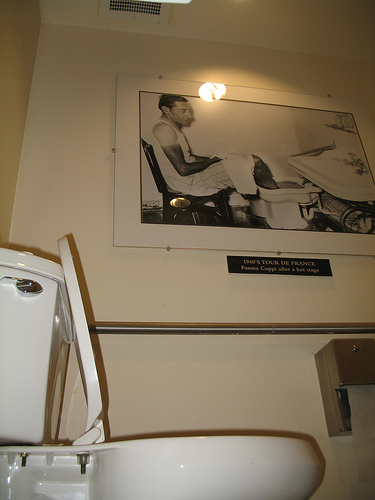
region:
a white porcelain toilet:
[0, 240, 332, 498]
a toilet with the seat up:
[44, 233, 337, 499]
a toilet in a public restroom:
[0, 197, 371, 495]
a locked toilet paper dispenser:
[310, 337, 373, 439]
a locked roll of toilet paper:
[310, 333, 373, 457]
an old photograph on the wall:
[88, 67, 373, 269]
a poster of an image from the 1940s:
[81, 63, 373, 285]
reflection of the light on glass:
[186, 72, 241, 127]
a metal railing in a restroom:
[88, 311, 373, 357]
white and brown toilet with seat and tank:
[1, 225, 329, 494]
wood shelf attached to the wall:
[312, 330, 370, 440]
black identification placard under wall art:
[208, 249, 336, 283]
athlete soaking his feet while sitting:
[110, 69, 374, 238]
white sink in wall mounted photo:
[274, 117, 369, 223]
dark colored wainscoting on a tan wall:
[88, 312, 370, 338]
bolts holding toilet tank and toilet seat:
[2, 438, 98, 476]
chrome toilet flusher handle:
[0, 269, 49, 302]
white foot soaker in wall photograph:
[236, 163, 321, 226]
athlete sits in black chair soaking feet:
[139, 94, 281, 222]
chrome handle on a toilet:
[0, 269, 48, 304]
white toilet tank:
[0, 240, 85, 452]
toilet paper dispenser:
[308, 323, 373, 444]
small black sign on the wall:
[223, 252, 336, 277]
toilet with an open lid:
[53, 227, 329, 499]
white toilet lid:
[52, 232, 112, 457]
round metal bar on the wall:
[75, 314, 374, 337]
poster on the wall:
[107, 78, 372, 255]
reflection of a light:
[193, 75, 230, 107]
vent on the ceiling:
[97, 2, 175, 31]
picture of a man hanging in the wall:
[110, 72, 374, 256]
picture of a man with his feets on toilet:
[116, 71, 374, 256]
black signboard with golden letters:
[228, 255, 332, 279]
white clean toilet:
[1, 232, 322, 498]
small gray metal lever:
[0, 273, 45, 294]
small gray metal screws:
[18, 450, 89, 473]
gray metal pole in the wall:
[76, 322, 373, 333]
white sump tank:
[0, 242, 76, 446]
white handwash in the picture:
[290, 142, 373, 205]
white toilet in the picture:
[247, 169, 330, 230]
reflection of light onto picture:
[194, 77, 230, 105]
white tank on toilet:
[3, 250, 57, 439]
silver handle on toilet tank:
[2, 273, 45, 295]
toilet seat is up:
[58, 232, 104, 439]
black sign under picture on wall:
[225, 256, 334, 276]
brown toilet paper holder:
[317, 340, 373, 433]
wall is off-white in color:
[147, 362, 262, 404]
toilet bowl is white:
[98, 444, 311, 483]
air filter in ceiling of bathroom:
[92, 3, 170, 23]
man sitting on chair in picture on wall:
[146, 96, 222, 206]